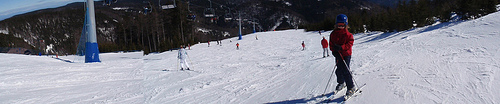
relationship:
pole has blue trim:
[76, 0, 104, 65] [83, 40, 101, 62]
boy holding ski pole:
[323, 13, 376, 92] [317, 59, 343, 99]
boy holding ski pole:
[323, 13, 376, 92] [339, 57, 357, 87]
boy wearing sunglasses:
[323, 13, 376, 92] [334, 20, 346, 27]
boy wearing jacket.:
[323, 13, 376, 92] [327, 24, 354, 56]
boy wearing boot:
[323, 13, 376, 92] [343, 81, 358, 99]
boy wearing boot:
[323, 13, 376, 92] [331, 77, 346, 93]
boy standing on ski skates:
[330, 12, 356, 92] [328, 82, 365, 100]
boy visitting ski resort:
[323, 13, 376, 92] [0, 1, 499, 101]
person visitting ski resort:
[316, 37, 334, 58] [0, 1, 499, 101]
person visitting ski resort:
[230, 39, 240, 54] [0, 1, 499, 101]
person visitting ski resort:
[173, 31, 190, 75] [0, 1, 499, 101]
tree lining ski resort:
[115, 11, 128, 51] [0, 1, 499, 101]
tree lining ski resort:
[131, 13, 141, 55] [0, 1, 499, 101]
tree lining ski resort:
[138, 13, 155, 54] [0, 1, 499, 101]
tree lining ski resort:
[155, 9, 171, 49] [0, 1, 499, 101]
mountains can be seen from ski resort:
[0, 0, 498, 64] [0, 1, 499, 101]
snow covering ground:
[4, 8, 498, 102] [0, 7, 499, 102]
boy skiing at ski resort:
[323, 13, 376, 92] [0, 1, 499, 101]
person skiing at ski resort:
[173, 31, 190, 75] [0, 1, 499, 101]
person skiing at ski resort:
[300, 37, 308, 56] [0, 1, 499, 101]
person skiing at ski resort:
[316, 37, 334, 58] [0, 1, 499, 101]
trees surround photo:
[7, 0, 499, 55] [1, 4, 498, 102]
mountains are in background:
[0, 0, 498, 64] [2, 2, 488, 58]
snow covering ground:
[4, 8, 498, 102] [4, 29, 497, 101]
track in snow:
[168, 75, 249, 97] [4, 8, 498, 102]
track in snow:
[244, 64, 298, 96] [4, 8, 498, 102]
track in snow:
[409, 83, 462, 101] [4, 8, 498, 102]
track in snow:
[437, 29, 482, 40] [4, 8, 498, 102]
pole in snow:
[76, 0, 104, 65] [4, 8, 498, 102]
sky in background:
[1, 1, 75, 21] [1, 3, 498, 43]